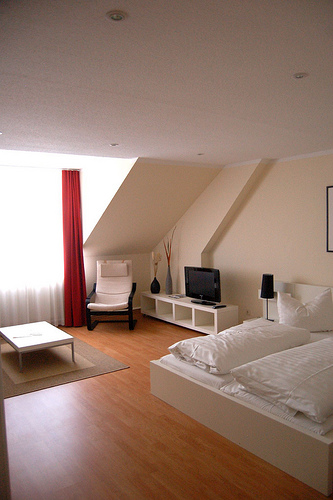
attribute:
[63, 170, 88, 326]
curtains — red in color, red, long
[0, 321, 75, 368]
table — white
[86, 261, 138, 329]
chair — white, black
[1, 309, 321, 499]
floor — hardwood, brown, light brown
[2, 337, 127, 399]
carpet — brown, tan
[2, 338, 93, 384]
inner carpet — beige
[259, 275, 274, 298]
lamp shade — black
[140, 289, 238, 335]
stand — white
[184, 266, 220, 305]
tv — black, flat screen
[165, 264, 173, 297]
vase — gray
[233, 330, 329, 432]
linens — white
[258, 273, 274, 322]
lamp — small